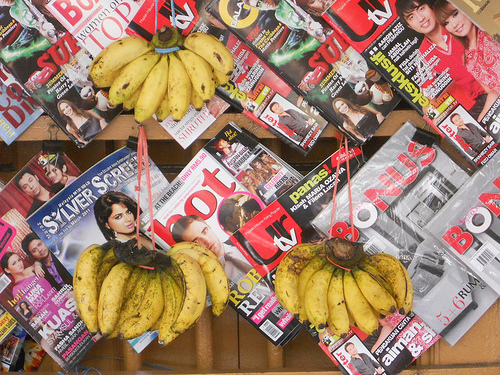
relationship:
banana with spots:
[272, 238, 322, 318] [287, 251, 306, 274]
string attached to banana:
[328, 135, 355, 242] [302, 257, 330, 325]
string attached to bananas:
[135, 125, 156, 250] [72, 237, 230, 347]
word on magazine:
[327, 140, 437, 245] [309, 121, 499, 346]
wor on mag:
[147, 164, 249, 249] [145, 144, 310, 349]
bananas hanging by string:
[72, 237, 107, 328] [327, 131, 356, 238]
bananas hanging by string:
[72, 237, 107, 328] [132, 121, 156, 250]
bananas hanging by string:
[106, 51, 163, 106] [152, 0, 180, 52]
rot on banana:
[72, 223, 235, 339] [75, 237, 228, 344]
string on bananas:
[151, 1, 185, 56] [82, 29, 240, 130]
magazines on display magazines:
[133, 122, 306, 340] [27, 162, 154, 333]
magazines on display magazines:
[234, 143, 431, 373] [27, 162, 154, 333]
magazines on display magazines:
[0, 148, 107, 368] [27, 162, 154, 333]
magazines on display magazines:
[423, 149, 498, 301] [27, 162, 154, 333]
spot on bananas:
[336, 296, 347, 309] [278, 245, 403, 331]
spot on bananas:
[285, 251, 309, 276] [278, 245, 403, 331]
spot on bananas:
[390, 290, 401, 300] [278, 245, 403, 331]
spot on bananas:
[282, 286, 292, 303] [278, 245, 403, 331]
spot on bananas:
[312, 294, 323, 304] [278, 245, 403, 331]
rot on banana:
[291, 257, 302, 272] [275, 240, 317, 325]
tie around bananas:
[149, 42, 185, 56] [79, 232, 244, 341]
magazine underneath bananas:
[354, 0, 500, 169] [282, 238, 407, 332]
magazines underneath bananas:
[28, 162, 154, 348] [72, 237, 107, 328]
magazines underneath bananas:
[423, 149, 498, 301] [282, 238, 407, 332]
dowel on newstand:
[193, 306, 213, 373] [2, 4, 497, 373]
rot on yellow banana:
[118, 79, 137, 92] [341, 270, 381, 338]